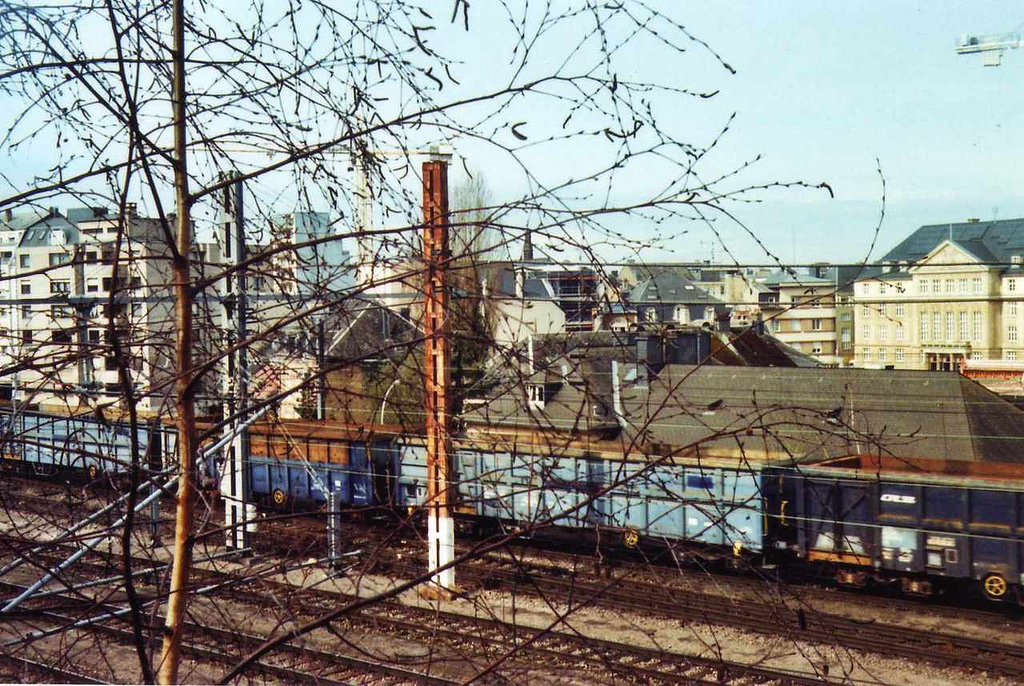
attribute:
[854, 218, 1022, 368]
building — white, beige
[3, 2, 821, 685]
tree — bare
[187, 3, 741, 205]
branch — brown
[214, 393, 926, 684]
branch — brown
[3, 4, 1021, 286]
sky — grey, blue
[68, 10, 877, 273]
cloud — white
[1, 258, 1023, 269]
power line — black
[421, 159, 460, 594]
tower — brown, rusty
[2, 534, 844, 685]
track — brown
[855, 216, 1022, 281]
roof — green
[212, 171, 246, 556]
pole — silver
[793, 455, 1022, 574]
car — navy blue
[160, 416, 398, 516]
train car — brown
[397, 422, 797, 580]
train car — light blue